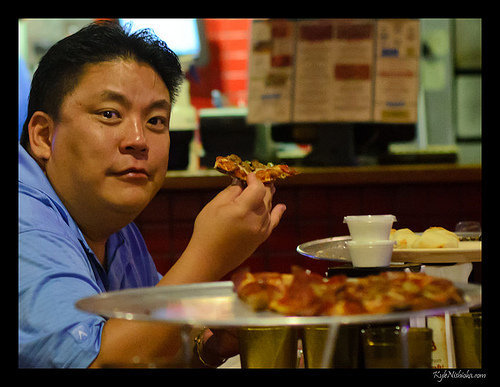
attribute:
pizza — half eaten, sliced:
[230, 269, 463, 317]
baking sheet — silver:
[73, 277, 485, 325]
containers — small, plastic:
[344, 212, 393, 266]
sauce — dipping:
[349, 223, 387, 237]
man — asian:
[23, 23, 288, 345]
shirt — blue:
[19, 148, 160, 374]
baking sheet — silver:
[299, 230, 481, 268]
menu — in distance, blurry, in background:
[251, 19, 418, 123]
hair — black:
[23, 25, 183, 117]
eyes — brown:
[99, 108, 165, 130]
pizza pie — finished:
[298, 232, 399, 267]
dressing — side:
[345, 214, 394, 241]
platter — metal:
[74, 274, 467, 353]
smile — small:
[105, 160, 163, 189]